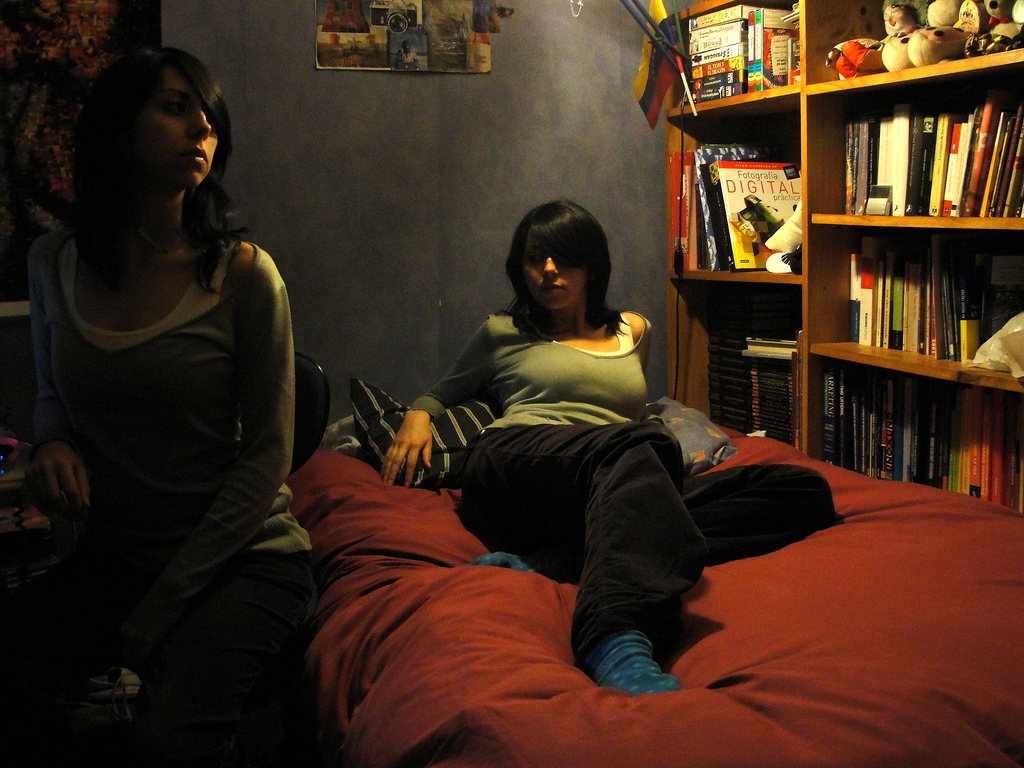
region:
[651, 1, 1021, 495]
the book shelves on the wall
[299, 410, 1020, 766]
the comforter on the bed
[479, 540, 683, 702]
the blue socks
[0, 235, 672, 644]
the green shirt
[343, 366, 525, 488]
a striped pillow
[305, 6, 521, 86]
a picture on the wall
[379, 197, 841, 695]
a lady laying down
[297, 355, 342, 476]
a black chair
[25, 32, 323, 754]
a girl sitting in the chair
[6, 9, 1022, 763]
a small bedroom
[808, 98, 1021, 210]
A row of books on a shelf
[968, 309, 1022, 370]
A white bag on a shelf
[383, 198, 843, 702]
A girl on a bed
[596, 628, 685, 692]
A blue sock on a girl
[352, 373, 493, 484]
A black and white striped pillow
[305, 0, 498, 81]
A picture hanging on a wall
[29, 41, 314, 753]
A girl sitting on a bed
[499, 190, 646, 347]
Girl has dark hair.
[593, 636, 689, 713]
Girl is wearing blue sock.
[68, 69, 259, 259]
Girl has long dark hair.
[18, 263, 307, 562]
Girl wearing gray shirt.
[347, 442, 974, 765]
Red bedspread on bed.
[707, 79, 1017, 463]
Wood book shelf near wall.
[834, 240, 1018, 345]
Books on bookshelf near bed.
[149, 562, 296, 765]
Girl is wearing black pants.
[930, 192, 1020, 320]
a book on the shelf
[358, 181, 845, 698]
woman sitting on the bed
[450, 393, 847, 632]
black pants of the woman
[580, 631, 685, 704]
blue colored sock of the woman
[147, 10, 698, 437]
blue colored wall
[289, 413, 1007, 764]
red colored blanket of the bed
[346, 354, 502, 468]
black and white striped pillow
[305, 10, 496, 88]
poster on the blue wall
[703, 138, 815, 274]
magazine that says digital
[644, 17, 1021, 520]
large wooden bookshelf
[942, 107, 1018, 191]
a book on a shelf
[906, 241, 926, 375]
a book on a shelf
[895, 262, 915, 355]
a book on a shelf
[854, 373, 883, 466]
a book on a shelf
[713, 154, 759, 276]
a book on a shelf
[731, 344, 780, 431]
a book on a shelf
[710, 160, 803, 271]
A book on a book shelf.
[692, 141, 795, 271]
A book on a book shelf.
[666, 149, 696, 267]
A book on a book shelf.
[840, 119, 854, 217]
A book on a book shelf.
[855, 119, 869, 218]
A book on a book shelf.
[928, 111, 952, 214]
A book on a book shelf.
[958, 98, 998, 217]
A book on a book shelf.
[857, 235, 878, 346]
A book on a book shelf.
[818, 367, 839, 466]
A book on a book shelf.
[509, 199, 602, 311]
person has a head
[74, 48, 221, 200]
person has a head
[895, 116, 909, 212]
book is on a shelf